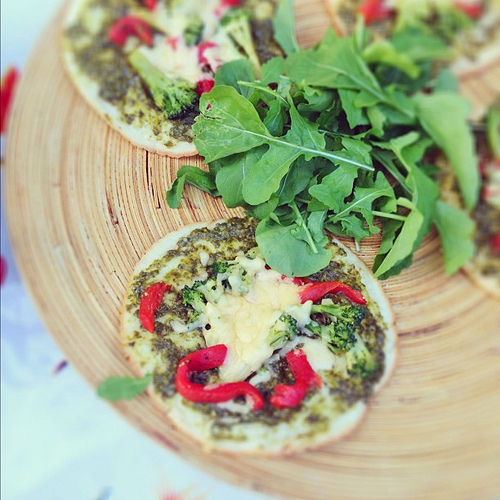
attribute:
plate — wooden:
[42, 135, 214, 307]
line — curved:
[45, 122, 112, 244]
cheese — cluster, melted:
[204, 272, 301, 378]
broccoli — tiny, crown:
[186, 216, 253, 259]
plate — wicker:
[1, 3, 488, 489]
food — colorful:
[131, 49, 489, 459]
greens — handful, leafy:
[159, 6, 487, 277]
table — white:
[7, 271, 118, 476]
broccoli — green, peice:
[108, 49, 213, 121]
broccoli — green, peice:
[314, 278, 377, 369]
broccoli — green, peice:
[177, 270, 271, 321]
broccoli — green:
[309, 302, 361, 352]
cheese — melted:
[234, 300, 280, 330]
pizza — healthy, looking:
[59, 0, 292, 159]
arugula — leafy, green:
[166, 0, 499, 282]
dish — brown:
[23, 73, 220, 300]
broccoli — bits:
[272, 302, 362, 346]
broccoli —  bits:
[177, 255, 251, 317]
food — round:
[57, 9, 213, 158]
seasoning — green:
[185, 217, 254, 244]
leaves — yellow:
[191, 81, 375, 203]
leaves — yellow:
[280, 30, 413, 120]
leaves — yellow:
[251, 214, 328, 278]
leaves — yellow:
[165, 162, 219, 208]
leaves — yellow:
[321, 171, 396, 231]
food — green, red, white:
[112, 200, 402, 457]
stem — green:
[227, 126, 379, 176]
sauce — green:
[185, 225, 265, 260]